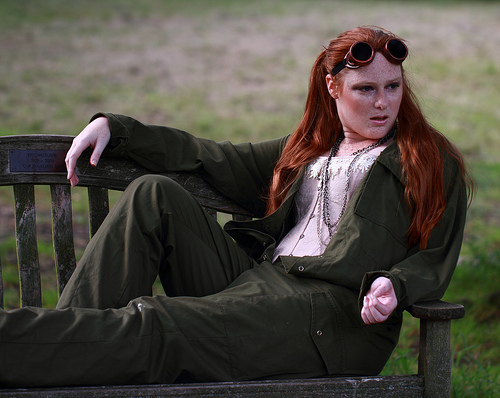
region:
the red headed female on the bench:
[12, 25, 471, 385]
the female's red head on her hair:
[263, 25, 477, 252]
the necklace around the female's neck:
[306, 131, 391, 248]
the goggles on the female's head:
[329, 35, 405, 77]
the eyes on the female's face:
[350, 77, 401, 93]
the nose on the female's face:
[373, 85, 389, 110]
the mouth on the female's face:
[366, 112, 389, 123]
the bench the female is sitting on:
[1, 127, 467, 395]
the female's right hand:
[61, 110, 116, 185]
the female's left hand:
[353, 271, 400, 330]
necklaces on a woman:
[272, 129, 392, 253]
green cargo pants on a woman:
[20, 196, 404, 384]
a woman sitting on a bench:
[0, 44, 483, 389]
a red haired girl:
[275, 2, 487, 263]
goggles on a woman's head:
[312, 20, 427, 94]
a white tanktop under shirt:
[261, 90, 418, 309]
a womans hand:
[318, 257, 430, 345]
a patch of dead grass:
[75, 45, 244, 90]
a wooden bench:
[0, 70, 114, 237]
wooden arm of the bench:
[402, 290, 479, 371]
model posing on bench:
[3, 34, 468, 383]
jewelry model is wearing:
[304, 127, 384, 269]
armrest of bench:
[405, 298, 456, 396]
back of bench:
[3, 134, 292, 304]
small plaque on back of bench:
[3, 139, 79, 181]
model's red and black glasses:
[324, 35, 416, 84]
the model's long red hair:
[258, 17, 470, 247]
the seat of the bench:
[3, 375, 421, 396]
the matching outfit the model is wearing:
[1, 121, 466, 392]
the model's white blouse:
[272, 149, 392, 284]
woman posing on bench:
[5, 23, 465, 381]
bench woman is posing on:
[0, 131, 457, 396]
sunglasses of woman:
[325, 31, 407, 71]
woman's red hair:
[260, 23, 480, 245]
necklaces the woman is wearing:
[285, 126, 405, 263]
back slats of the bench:
[5, 183, 129, 310]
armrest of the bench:
[410, 301, 463, 373]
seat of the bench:
[2, 376, 442, 396]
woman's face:
[324, 48, 410, 145]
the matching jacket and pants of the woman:
[2, 102, 467, 386]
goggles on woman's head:
[337, 33, 411, 68]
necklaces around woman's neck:
[320, 142, 360, 239]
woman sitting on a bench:
[17, 23, 471, 384]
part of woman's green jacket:
[152, 125, 278, 212]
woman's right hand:
[360, 275, 393, 329]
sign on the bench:
[2, 141, 65, 175]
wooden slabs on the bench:
[11, 183, 71, 304]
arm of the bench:
[409, 297, 460, 394]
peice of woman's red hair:
[400, 112, 458, 248]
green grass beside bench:
[457, 289, 498, 319]